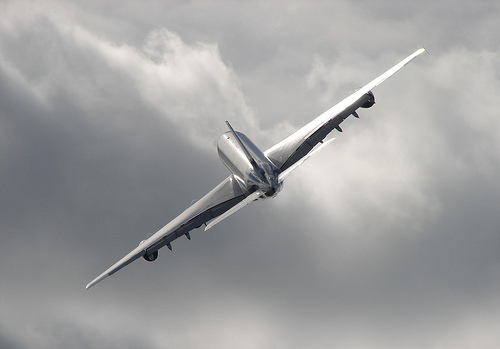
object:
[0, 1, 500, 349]
cloud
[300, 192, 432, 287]
sky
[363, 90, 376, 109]
black wheel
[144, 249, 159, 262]
black wheel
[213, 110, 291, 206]
tail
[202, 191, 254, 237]
wing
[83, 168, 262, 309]
wing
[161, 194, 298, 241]
wall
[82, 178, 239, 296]
plane wing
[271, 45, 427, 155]
light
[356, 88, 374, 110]
turbines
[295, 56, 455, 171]
wing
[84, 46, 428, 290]
airplane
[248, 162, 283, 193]
tail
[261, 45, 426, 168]
wing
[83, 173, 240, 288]
wing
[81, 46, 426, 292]
transportation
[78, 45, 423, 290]
wings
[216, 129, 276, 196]
body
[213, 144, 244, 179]
shadow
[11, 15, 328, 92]
sky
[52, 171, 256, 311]
wing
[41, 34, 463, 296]
silverplane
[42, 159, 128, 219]
grey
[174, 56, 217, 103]
white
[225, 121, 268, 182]
tail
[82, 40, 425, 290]
plane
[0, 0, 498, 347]
sky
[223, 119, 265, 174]
back wings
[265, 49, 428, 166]
right wing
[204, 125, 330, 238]
tail